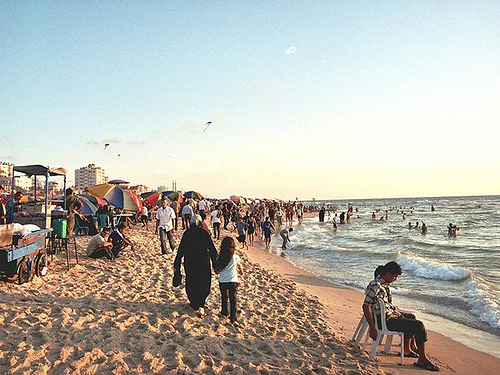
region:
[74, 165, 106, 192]
very tall building off the shore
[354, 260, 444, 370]
two people sitting in plastic lawn chairs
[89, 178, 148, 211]
colored umbrella to protect from sun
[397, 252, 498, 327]
large rolling waves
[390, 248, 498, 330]
tide coming in to shore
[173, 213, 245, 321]
holding girls hand while walking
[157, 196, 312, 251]
large gathering of people at water front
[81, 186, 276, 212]
rows of umbrellas line the beach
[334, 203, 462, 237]
people swimming in water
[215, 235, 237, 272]
long hair blowing in wind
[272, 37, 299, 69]
cloud in the sky.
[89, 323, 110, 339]
footprints in the sand.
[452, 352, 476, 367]
sand on the beach.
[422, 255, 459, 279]
waves in the water.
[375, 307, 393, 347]
chair on the beach.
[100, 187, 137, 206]
umbrella on the beach.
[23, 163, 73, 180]
canopy over the stand.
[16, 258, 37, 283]
wheel on the cart.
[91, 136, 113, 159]
kite in the sky.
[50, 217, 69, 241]
cooler on the table.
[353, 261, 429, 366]
a couple sitting in chairs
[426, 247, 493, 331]
a ocean wave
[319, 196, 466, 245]
people in the water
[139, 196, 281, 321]
people on the beach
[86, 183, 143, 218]
a red yellow and blue umbrella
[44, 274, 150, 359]
tracks in the sand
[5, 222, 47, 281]
a blue wagon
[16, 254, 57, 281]
wooden wagon wheels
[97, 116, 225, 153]
kites in the sky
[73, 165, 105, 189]
a white building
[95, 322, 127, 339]
footprints in the sand.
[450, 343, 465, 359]
sand on the beach.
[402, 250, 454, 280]
waves in the water.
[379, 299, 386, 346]
chair on the beach.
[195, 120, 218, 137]
kite in the air.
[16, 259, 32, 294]
wheel of the cart.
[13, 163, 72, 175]
canopy on the stand.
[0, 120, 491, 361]
The people are enjoying the beach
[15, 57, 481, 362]
The people are walking in the sand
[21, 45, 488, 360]
The people are swimming in the water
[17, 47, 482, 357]
The people are enjoying their day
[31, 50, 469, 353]
The people are enjoying the sunshine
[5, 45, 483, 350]
The people are in a coastal area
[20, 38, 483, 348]
The people are close to the ocean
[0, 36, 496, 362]
The people are enjoying some recreation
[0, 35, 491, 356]
Some people are getting very wet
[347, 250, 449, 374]
Some people are sitting in chairs